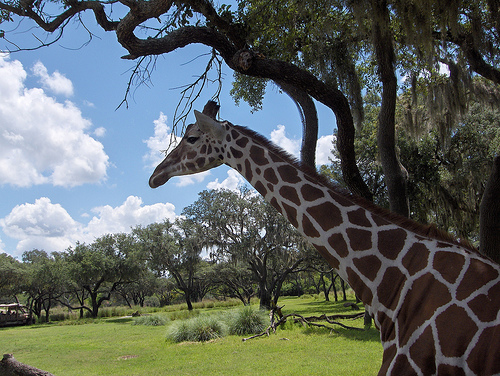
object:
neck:
[228, 133, 459, 308]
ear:
[201, 100, 220, 120]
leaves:
[226, 233, 258, 258]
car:
[0, 304, 28, 330]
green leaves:
[164, 306, 267, 342]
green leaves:
[128, 312, 168, 326]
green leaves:
[0, 230, 151, 303]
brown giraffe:
[148, 101, 500, 375]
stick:
[307, 319, 339, 336]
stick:
[302, 312, 366, 321]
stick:
[322, 316, 365, 331]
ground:
[1, 286, 382, 376]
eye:
[186, 136, 200, 145]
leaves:
[408, 105, 444, 153]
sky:
[0, 0, 492, 259]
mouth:
[148, 173, 167, 189]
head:
[147, 100, 228, 189]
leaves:
[2, 219, 172, 295]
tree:
[0, 1, 500, 321]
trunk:
[374, 41, 409, 222]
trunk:
[281, 64, 375, 213]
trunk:
[278, 76, 319, 172]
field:
[0, 0, 500, 376]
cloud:
[0, 0, 347, 259]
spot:
[244, 140, 273, 166]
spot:
[264, 166, 283, 185]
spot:
[304, 184, 329, 204]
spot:
[342, 205, 372, 230]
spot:
[403, 238, 435, 277]